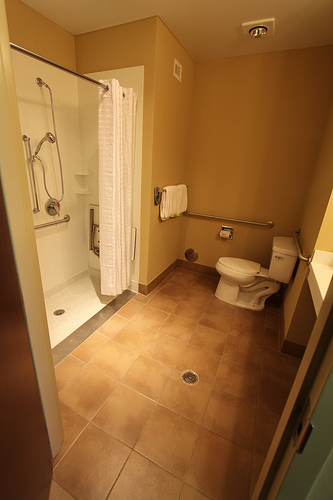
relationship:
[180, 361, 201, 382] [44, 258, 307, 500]
drain on ceramicfloor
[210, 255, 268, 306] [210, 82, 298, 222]
toilet next to wall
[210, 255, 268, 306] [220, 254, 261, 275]
toilet with closedlid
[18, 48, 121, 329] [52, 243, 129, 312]
shower with no bathtub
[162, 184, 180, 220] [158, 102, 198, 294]
bathtowels hanging on wall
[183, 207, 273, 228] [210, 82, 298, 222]
handle along wall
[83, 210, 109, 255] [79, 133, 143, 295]
chair on showerwall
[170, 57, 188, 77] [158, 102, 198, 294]
airvent on wall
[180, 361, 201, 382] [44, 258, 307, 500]
floordrain on ceramicfloor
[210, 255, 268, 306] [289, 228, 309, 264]
toilet with silvergrabbar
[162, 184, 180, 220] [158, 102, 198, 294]
bathtowels on wall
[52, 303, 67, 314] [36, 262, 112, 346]
drain in showerfloor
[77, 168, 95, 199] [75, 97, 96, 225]
smallshelves in corner of shower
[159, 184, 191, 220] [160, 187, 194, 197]
towel hanging on bar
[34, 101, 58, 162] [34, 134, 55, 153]
showerfaucet with metal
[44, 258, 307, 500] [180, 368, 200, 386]
ceramicfloor with drain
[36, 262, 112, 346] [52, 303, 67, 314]
showerfloor with draingate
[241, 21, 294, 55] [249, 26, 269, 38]
lightfixture with edging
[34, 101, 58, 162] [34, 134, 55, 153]
showerfaucet of metal